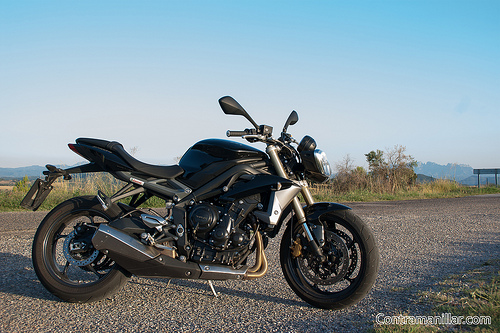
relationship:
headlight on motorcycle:
[305, 135, 335, 183] [17, 89, 385, 314]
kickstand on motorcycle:
[205, 276, 219, 299] [17, 89, 385, 314]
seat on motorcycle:
[73, 134, 187, 184] [17, 89, 385, 314]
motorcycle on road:
[17, 89, 385, 314] [3, 195, 500, 332]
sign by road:
[472, 165, 500, 179] [3, 195, 500, 332]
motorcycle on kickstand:
[17, 89, 385, 314] [205, 276, 219, 299]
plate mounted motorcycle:
[17, 179, 55, 212] [17, 89, 385, 314]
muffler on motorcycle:
[86, 220, 251, 289] [17, 89, 385, 314]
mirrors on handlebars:
[215, 91, 251, 124] [224, 120, 260, 143]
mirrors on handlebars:
[281, 108, 304, 132] [284, 132, 295, 142]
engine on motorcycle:
[183, 192, 251, 260] [17, 89, 385, 314]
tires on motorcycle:
[275, 197, 380, 309] [17, 89, 385, 314]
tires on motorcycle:
[26, 186, 140, 307] [17, 89, 385, 314]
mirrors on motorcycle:
[215, 91, 251, 124] [17, 89, 385, 314]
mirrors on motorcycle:
[281, 108, 304, 132] [17, 89, 385, 314]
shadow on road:
[2, 246, 94, 309] [3, 195, 500, 332]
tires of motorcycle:
[275, 197, 380, 309] [17, 89, 385, 314]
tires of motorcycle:
[26, 186, 140, 307] [17, 89, 385, 314]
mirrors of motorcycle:
[215, 91, 251, 124] [17, 89, 385, 314]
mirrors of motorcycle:
[281, 108, 304, 132] [17, 89, 385, 314]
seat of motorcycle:
[73, 134, 187, 184] [17, 89, 385, 314]